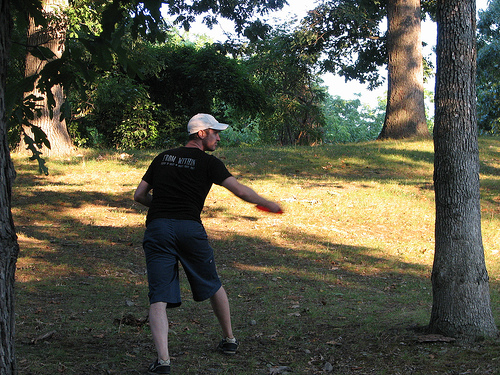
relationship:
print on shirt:
[160, 152, 197, 170] [139, 144, 234, 219]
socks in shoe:
[222, 333, 237, 347] [216, 335, 239, 355]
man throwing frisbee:
[132, 112, 284, 375] [253, 201, 284, 216]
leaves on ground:
[0, 137, 500, 375] [10, 137, 499, 373]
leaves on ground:
[266, 359, 289, 373] [10, 137, 499, 373]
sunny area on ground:
[297, 176, 442, 243] [10, 137, 499, 373]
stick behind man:
[34, 317, 57, 350] [138, 98, 247, 338]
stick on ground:
[34, 317, 57, 350] [10, 137, 499, 373]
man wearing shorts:
[132, 112, 284, 375] [141, 217, 223, 307]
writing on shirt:
[155, 146, 202, 178] [139, 144, 234, 219]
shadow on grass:
[244, 242, 311, 274] [0, 132, 498, 370]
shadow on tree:
[386, 5, 418, 151] [381, 2, 430, 141]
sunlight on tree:
[48, 123, 75, 150] [28, 5, 80, 159]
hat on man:
[183, 108, 239, 134] [111, 103, 299, 330]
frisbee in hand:
[254, 201, 286, 217] [263, 191, 280, 211]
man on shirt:
[132, 112, 284, 375] [130, 132, 223, 211]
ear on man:
[198, 125, 206, 138] [117, 99, 269, 366]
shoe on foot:
[219, 340, 240, 352] [138, 351, 185, 372]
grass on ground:
[0, 130, 500, 375] [10, 137, 499, 373]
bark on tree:
[427, 0, 499, 338] [431, 0, 498, 345]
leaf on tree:
[121, 51, 138, 64] [78, 40, 265, 148]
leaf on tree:
[104, 87, 114, 107] [78, 40, 265, 148]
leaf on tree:
[135, 122, 150, 137] [78, 40, 265, 148]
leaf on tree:
[187, 64, 201, 84] [78, 40, 265, 148]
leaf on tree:
[213, 71, 225, 85] [78, 40, 265, 148]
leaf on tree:
[134, 130, 140, 135] [63, 0, 330, 147]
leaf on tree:
[119, 51, 137, 67] [82, 11, 156, 158]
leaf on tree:
[139, 104, 143, 111] [6, 0, 291, 170]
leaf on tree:
[194, 54, 233, 94] [63, 0, 330, 147]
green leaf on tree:
[54, 5, 496, 152] [63, 0, 330, 147]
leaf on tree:
[255, 51, 262, 56] [245, 6, 325, 146]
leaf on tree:
[257, 55, 267, 61] [245, 6, 325, 146]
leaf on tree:
[258, 55, 266, 62] [245, 6, 325, 146]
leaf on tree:
[270, 48, 277, 53] [245, 6, 325, 146]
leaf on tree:
[265, 84, 270, 89] [245, 6, 325, 146]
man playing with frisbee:
[132, 112, 284, 375] [255, 197, 283, 211]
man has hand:
[132, 112, 284, 375] [263, 201, 277, 211]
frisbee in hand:
[255, 202, 284, 215] [263, 201, 277, 211]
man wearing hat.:
[132, 112, 284, 375] [173, 102, 238, 148]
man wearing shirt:
[124, 104, 291, 365] [139, 144, 234, 219]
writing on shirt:
[160, 154, 195, 170] [139, 144, 234, 219]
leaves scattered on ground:
[0, 137, 500, 375] [10, 137, 499, 373]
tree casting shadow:
[419, 0, 498, 344] [0, 169, 500, 375]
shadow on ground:
[0, 169, 500, 375] [10, 137, 499, 373]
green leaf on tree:
[0, 0, 500, 175] [63, 0, 330, 147]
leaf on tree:
[149, 69, 177, 91] [72, 27, 274, 159]